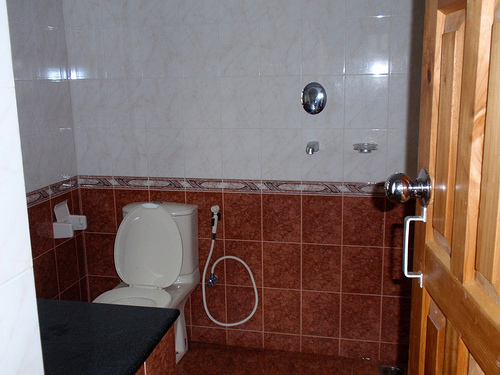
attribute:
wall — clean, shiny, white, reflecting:
[95, 29, 251, 161]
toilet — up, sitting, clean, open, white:
[95, 208, 206, 307]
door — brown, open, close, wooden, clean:
[418, 34, 497, 277]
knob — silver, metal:
[372, 168, 441, 218]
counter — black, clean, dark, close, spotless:
[60, 302, 165, 367]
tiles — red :
[264, 197, 327, 266]